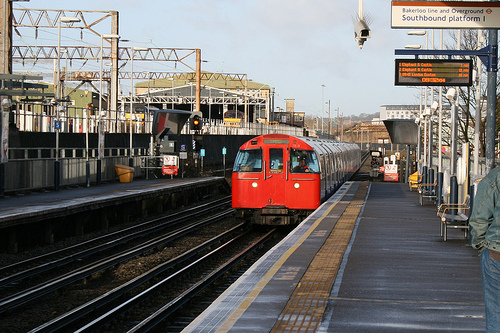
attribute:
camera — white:
[325, 12, 390, 56]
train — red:
[227, 132, 367, 232]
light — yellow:
[189, 107, 204, 140]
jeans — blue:
[471, 244, 499, 331]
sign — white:
[388, 0, 499, 32]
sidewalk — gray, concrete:
[183, 169, 491, 331]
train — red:
[230, 128, 389, 222]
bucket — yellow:
[110, 158, 145, 187]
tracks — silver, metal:
[22, 223, 272, 331]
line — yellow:
[211, 179, 354, 331]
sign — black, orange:
[383, 51, 482, 97]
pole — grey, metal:
[190, 45, 205, 115]